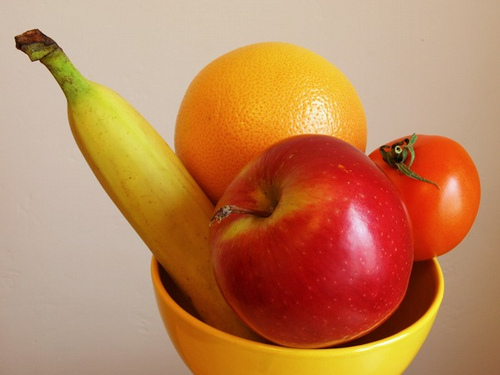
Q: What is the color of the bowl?
A: Yellow.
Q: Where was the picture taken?
A: Inddor.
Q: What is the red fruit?
A: Apple.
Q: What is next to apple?
A: Banana.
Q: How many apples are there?
A: 1.